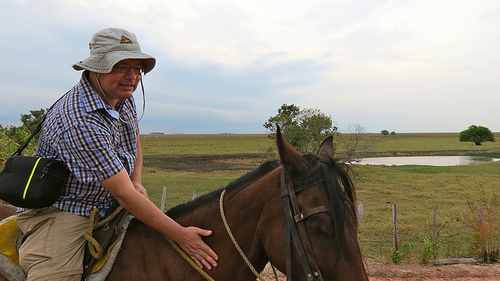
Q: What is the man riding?
A: Horse.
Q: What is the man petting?
A: Horse.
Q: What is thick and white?
A: Clouds.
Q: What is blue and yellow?
A: Shirt.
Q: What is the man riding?
A: Horse.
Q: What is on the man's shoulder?
A: Bag.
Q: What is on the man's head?
A: Hat.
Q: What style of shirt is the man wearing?
A: Plaid.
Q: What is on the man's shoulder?
A: Bag.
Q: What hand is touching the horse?
A: Right.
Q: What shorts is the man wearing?
A: Khaki.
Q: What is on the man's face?
A: Glasses.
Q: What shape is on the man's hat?
A: Triangle.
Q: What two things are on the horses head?
A: Ears.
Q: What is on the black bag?
A: Yellow stripe.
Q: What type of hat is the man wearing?
A: Safari.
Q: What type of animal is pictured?
A: A horse.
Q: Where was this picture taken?
A: At a field.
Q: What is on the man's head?
A: A hat.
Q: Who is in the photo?
A: A man.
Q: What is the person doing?
A: Riding a horse.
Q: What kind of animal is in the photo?
A: Horse.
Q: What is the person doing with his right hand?
A: Patting the horse's neck.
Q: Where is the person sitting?
A: On a horse.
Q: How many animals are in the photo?
A: One.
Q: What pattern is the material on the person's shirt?
A: Plaid.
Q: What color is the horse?
A: Brown.